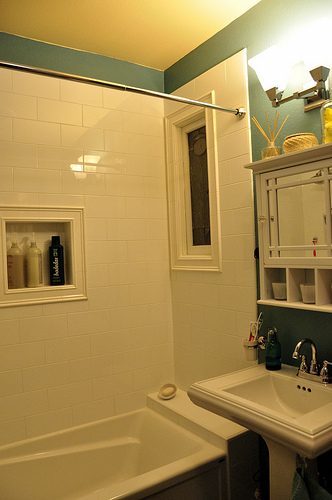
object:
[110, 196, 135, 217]
tiles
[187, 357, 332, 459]
sink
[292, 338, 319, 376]
faucet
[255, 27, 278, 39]
wall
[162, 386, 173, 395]
soap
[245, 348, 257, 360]
cup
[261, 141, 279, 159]
bottle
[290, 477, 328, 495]
towel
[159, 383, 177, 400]
dish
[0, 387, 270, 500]
tub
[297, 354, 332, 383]
handles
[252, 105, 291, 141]
candles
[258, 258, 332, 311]
shelf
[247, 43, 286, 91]
light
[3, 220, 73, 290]
ledge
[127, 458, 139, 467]
plug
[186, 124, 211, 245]
mirror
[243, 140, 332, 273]
shelves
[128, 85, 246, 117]
rod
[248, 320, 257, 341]
toothpaste